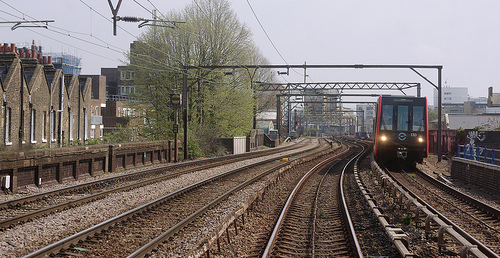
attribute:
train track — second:
[256, 136, 366, 256]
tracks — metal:
[1, 136, 498, 254]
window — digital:
[390, 96, 416, 106]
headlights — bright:
[379, 134, 425, 144]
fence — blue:
[458, 140, 498, 165]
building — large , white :
[432, 84, 471, 106]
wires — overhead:
[1, 0, 290, 68]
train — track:
[366, 90, 438, 176]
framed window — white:
[25, 107, 42, 146]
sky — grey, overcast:
[6, 2, 493, 97]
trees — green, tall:
[137, 27, 272, 158]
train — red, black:
[335, 74, 460, 174]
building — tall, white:
[431, 85, 468, 105]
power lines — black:
[0, 3, 304, 88]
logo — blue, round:
[396, 130, 411, 143]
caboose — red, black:
[338, 57, 455, 165]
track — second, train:
[7, 125, 494, 256]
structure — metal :
[264, 77, 365, 95]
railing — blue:
[460, 141, 498, 168]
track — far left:
[4, 123, 321, 250]